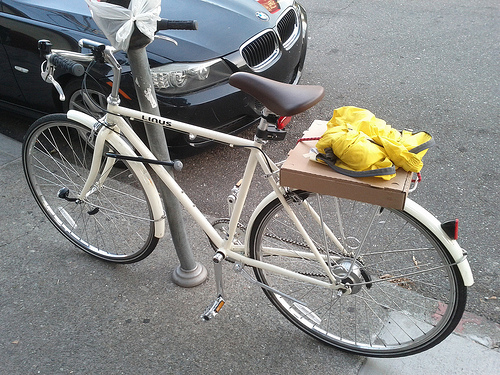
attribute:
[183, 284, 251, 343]
pedal — Silver 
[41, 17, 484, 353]
bicycle — leaning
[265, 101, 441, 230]
cardboard box — on back 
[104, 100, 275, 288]
frame — white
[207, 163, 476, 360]
tire — back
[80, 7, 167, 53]
plastic — wrapped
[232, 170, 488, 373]
wheel — back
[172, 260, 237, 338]
pedal — silver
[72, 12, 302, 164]
car — black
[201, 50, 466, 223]
road — paved